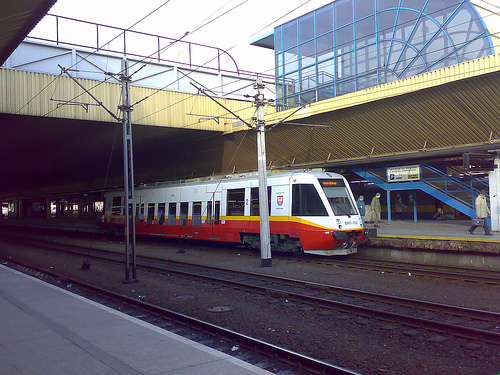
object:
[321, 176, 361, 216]
windshield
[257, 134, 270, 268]
pole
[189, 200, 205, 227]
windows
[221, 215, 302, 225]
strip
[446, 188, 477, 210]
steps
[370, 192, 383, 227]
man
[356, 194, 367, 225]
men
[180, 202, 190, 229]
windows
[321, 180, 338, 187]
sign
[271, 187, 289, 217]
logo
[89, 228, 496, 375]
tracks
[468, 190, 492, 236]
man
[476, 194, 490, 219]
coat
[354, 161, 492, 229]
staircase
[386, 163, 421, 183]
sign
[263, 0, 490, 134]
wall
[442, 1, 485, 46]
windows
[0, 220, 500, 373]
lanes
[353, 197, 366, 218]
jacket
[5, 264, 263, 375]
platform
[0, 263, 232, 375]
stripe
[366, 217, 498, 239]
platform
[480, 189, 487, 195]
hat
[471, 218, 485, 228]
briefcase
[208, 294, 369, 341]
gravel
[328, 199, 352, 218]
wiper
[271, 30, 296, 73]
window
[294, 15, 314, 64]
window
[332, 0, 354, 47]
window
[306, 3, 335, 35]
window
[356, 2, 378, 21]
window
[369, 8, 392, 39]
window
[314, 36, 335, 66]
window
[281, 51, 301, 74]
window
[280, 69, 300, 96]
window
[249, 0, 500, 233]
building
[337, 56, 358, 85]
window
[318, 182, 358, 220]
window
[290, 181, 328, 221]
window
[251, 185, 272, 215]
window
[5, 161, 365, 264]
train